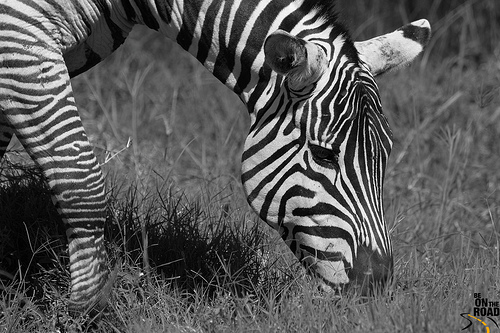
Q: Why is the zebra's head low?
A: To graze.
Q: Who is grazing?
A: The zebra.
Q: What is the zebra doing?
A: Grazing.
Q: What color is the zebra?
A: Black and white.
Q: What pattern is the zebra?
A: Striped.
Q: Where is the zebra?
A: In the grass.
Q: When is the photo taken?
A: Daytime.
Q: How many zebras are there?
A: 1.